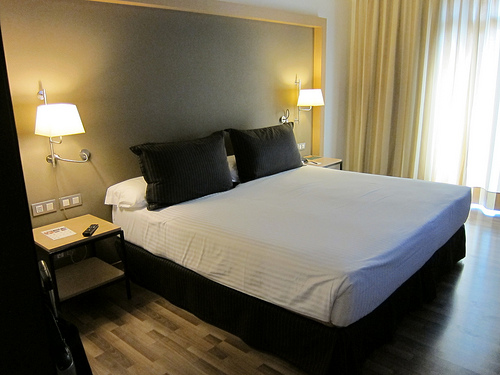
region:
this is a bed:
[90, 109, 492, 337]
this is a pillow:
[128, 102, 252, 224]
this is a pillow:
[232, 108, 300, 186]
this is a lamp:
[31, 85, 95, 180]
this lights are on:
[27, 73, 105, 180]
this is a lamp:
[280, 69, 344, 133]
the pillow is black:
[124, 131, 254, 218]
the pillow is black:
[234, 102, 306, 190]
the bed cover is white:
[72, 159, 489, 337]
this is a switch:
[21, 195, 65, 220]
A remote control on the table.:
[82, 218, 100, 243]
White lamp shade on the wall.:
[23, 102, 87, 139]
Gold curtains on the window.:
[356, 18, 426, 164]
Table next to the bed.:
[41, 208, 133, 288]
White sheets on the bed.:
[223, 197, 418, 284]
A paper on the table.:
[42, 222, 70, 244]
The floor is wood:
[98, 306, 190, 371]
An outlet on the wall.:
[23, 193, 107, 214]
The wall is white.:
[322, 16, 366, 146]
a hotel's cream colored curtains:
[347, 0, 499, 147]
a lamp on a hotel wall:
[280, 63, 331, 123]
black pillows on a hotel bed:
[135, 126, 303, 186]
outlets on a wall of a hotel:
[20, 196, 92, 213]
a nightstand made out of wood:
[13, 218, 134, 332]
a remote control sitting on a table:
[80, 222, 103, 247]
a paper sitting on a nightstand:
[40, 224, 78, 244]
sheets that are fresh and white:
[262, 194, 389, 334]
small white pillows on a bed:
[99, 173, 150, 215]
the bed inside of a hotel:
[111, 97, 479, 347]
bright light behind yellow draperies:
[345, 1, 495, 212]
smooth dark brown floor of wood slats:
[80, 206, 495, 367]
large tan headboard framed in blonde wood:
[0, 0, 341, 230]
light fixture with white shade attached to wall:
[25, 80, 91, 166]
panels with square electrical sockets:
[30, 190, 80, 215]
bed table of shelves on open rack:
[35, 216, 127, 312]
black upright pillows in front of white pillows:
[130, 120, 302, 210]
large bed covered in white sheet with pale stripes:
[111, 146, 467, 316]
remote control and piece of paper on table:
[41, 220, 96, 240]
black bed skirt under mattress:
[117, 225, 472, 355]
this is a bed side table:
[37, 206, 147, 337]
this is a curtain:
[356, 0, 491, 190]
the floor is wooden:
[104, 299, 206, 361]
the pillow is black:
[226, 101, 331, 229]